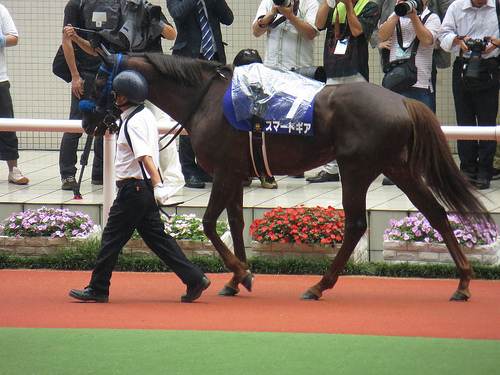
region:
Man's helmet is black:
[105, 56, 156, 116]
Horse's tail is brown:
[400, 100, 485, 235]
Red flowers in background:
[252, 197, 347, 252]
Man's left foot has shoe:
[55, 275, 116, 305]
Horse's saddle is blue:
[215, 40, 337, 147]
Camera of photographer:
[388, 5, 430, 16]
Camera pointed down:
[454, 21, 490, 82]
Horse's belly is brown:
[193, 119, 345, 186]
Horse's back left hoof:
[296, 251, 340, 309]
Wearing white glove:
[150, 177, 175, 203]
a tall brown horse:
[43, 43, 475, 293]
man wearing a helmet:
[86, 59, 163, 146]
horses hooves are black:
[185, 255, 339, 315]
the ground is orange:
[136, 264, 415, 329]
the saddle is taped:
[202, 40, 317, 134]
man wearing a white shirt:
[75, 62, 175, 209]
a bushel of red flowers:
[232, 187, 365, 249]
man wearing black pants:
[58, 166, 226, 310]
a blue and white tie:
[175, 0, 222, 55]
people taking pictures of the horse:
[373, 2, 498, 60]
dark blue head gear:
[108, 65, 153, 107]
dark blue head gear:
[112, 77, 165, 121]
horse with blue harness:
[80, 45, 140, 132]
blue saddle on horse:
[228, 69, 326, 135]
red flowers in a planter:
[249, 201, 342, 251]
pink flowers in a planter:
[3, 201, 78, 234]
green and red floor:
[24, 265, 492, 362]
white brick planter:
[0, 232, 83, 264]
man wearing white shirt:
[99, 66, 182, 244]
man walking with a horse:
[79, 45, 252, 306]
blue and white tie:
[195, 6, 225, 67]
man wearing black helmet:
[101, 72, 147, 109]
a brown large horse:
[42, 23, 472, 335]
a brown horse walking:
[53, 32, 495, 295]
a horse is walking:
[34, 12, 422, 359]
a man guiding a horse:
[67, 7, 447, 373]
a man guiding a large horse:
[51, 2, 496, 315]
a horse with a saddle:
[53, 28, 485, 317]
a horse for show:
[47, 22, 417, 368]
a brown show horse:
[3, 24, 487, 354]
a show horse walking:
[54, 34, 491, 359]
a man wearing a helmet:
[12, 45, 332, 277]